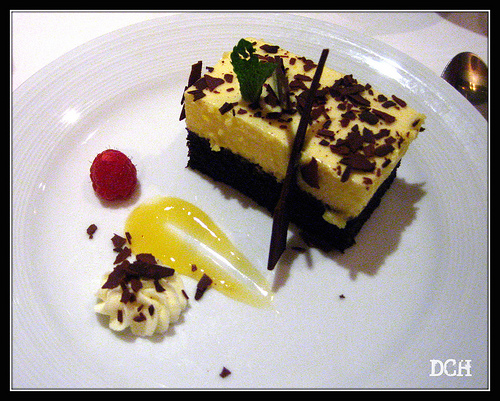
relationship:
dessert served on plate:
[81, 29, 427, 340] [11, 10, 498, 399]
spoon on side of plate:
[443, 48, 488, 116] [11, 10, 498, 399]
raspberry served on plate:
[88, 147, 140, 202] [11, 10, 498, 399]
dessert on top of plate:
[81, 29, 427, 340] [11, 10, 498, 399]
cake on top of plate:
[178, 34, 427, 270] [11, 10, 498, 399]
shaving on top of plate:
[263, 48, 329, 277] [11, 10, 498, 399]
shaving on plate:
[263, 48, 329, 277] [11, 10, 498, 399]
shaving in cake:
[263, 48, 329, 277] [178, 34, 427, 270]